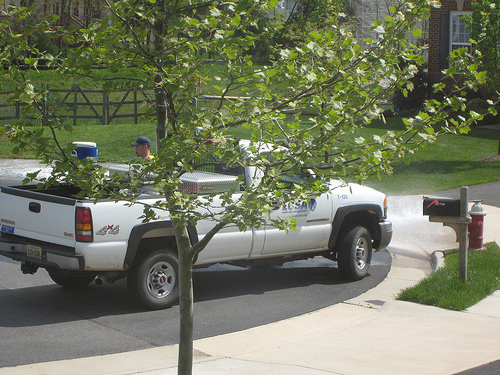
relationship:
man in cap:
[134, 136, 161, 174] [130, 134, 153, 151]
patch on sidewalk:
[406, 238, 498, 318] [359, 311, 496, 369]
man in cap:
[128, 134, 165, 172] [133, 136, 153, 147]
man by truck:
[128, 134, 165, 172] [4, 129, 397, 318]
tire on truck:
[125, 249, 193, 308] [4, 129, 397, 318]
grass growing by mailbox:
[415, 276, 476, 307] [416, 183, 470, 292]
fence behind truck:
[8, 80, 193, 127] [4, 129, 397, 318]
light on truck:
[71, 203, 91, 242] [5, 140, 393, 312]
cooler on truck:
[63, 137, 103, 180] [4, 129, 397, 318]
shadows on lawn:
[372, 151, 496, 191] [329, 123, 497, 207]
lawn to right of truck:
[329, 123, 497, 207] [4, 129, 397, 318]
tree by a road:
[17, 5, 362, 373] [10, 278, 314, 368]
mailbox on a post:
[417, 191, 477, 221] [433, 213, 473, 283]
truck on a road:
[6, 119, 421, 293] [54, 266, 405, 373]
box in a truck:
[146, 162, 254, 229] [10, 106, 401, 326]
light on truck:
[70, 199, 113, 262] [21, 120, 384, 312]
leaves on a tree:
[191, 46, 328, 167] [90, 20, 392, 371]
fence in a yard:
[0, 80, 157, 127] [33, 63, 207, 145]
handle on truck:
[20, 202, 50, 222] [4, 129, 397, 318]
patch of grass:
[395, 241, 499, 312] [425, 270, 469, 302]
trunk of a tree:
[178, 265, 193, 372] [37, 10, 440, 373]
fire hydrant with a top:
[469, 207, 491, 257] [462, 199, 485, 214]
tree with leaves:
[1, 5, 500, 373] [298, 49, 391, 128]